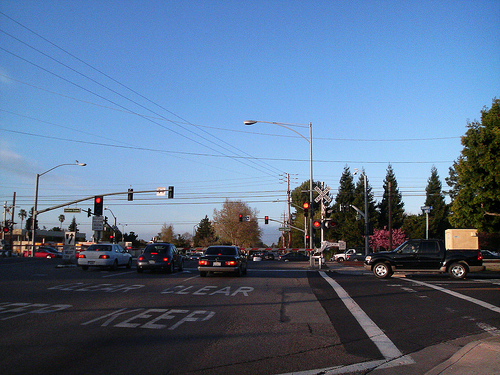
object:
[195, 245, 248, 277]
car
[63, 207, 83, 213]
sign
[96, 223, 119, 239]
tree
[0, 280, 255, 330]
notice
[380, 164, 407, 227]
trees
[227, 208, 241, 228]
leaves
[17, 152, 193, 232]
lighting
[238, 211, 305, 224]
lights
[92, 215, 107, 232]
sign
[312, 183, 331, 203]
sign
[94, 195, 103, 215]
light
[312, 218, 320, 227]
light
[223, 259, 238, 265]
brake lights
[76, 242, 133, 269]
car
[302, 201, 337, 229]
signal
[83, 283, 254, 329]
writing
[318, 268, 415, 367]
lines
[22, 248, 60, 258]
car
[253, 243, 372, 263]
crossing rail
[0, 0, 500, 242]
sky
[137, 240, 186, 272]
cars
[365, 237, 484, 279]
black truck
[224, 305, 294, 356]
asphalt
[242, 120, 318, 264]
street light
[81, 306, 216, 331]
word keep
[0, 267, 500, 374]
street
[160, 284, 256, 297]
word clear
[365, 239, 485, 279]
pickup truck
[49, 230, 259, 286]
traffic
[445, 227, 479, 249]
container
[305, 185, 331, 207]
signs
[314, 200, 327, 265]
pole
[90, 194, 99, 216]
traffic signal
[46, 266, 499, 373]
intersection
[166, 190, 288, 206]
power wires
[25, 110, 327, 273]
utility poles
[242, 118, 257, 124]
light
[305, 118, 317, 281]
support pole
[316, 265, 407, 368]
crosswalk